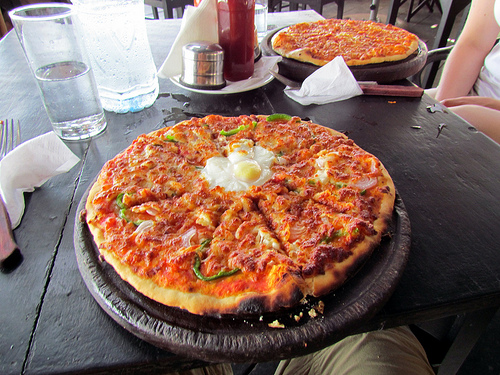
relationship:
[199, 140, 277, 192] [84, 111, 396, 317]
egg on pizza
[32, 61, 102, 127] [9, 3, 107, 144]
water in glass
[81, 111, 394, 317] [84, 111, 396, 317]
crust on pizza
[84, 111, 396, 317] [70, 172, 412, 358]
pizza on top of tray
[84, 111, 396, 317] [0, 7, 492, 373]
pizza on top of table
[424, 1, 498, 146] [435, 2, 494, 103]
person has arm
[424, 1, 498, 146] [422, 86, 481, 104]
person has leg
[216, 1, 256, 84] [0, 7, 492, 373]
ketchup on table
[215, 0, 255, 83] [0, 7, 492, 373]
bottle on table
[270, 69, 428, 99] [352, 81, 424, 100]
silverware with handle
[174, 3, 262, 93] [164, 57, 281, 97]
condiments on top of plate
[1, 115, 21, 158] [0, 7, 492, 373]
fork on table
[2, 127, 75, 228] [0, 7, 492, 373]
napkin on table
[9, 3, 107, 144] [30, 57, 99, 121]
glass of water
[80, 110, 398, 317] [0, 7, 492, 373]
pizza pie on table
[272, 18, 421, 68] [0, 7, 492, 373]
pizza pie on table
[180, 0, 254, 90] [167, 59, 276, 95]
bottles on plate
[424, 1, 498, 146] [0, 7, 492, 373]
person sitting at table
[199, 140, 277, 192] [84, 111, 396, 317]
egg in middle of pizza